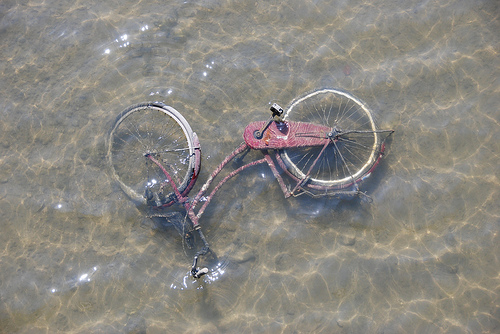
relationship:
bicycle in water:
[100, 86, 396, 279] [0, 0, 499, 332]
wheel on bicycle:
[104, 101, 200, 207] [117, 82, 385, 282]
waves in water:
[272, 235, 493, 326] [0, 0, 499, 332]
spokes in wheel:
[122, 124, 173, 181] [104, 101, 200, 207]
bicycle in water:
[105, 100, 395, 260] [0, 0, 499, 332]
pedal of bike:
[245, 99, 300, 135] [56, 57, 494, 283]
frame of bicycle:
[137, 113, 404, 280] [100, 86, 396, 279]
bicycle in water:
[100, 86, 396, 279] [2, 2, 494, 283]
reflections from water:
[74, 27, 246, 99] [74, 31, 442, 298]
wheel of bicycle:
[104, 101, 200, 207] [103, 83, 395, 287]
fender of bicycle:
[289, 172, 375, 202] [103, 83, 395, 287]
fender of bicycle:
[136, 125, 204, 215] [103, 83, 395, 287]